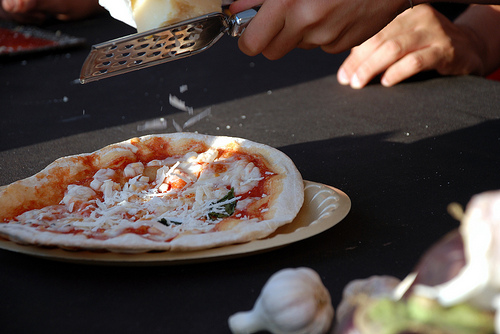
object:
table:
[0, 20, 499, 332]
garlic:
[67, 183, 94, 201]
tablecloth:
[0, 15, 499, 332]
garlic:
[443, 190, 498, 309]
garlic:
[132, 81, 221, 138]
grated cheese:
[0, 133, 286, 236]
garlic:
[226, 264, 337, 334]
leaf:
[210, 183, 267, 220]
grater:
[77, 1, 269, 89]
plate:
[0, 177, 354, 264]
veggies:
[348, 284, 494, 334]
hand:
[230, 0, 414, 60]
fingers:
[331, 24, 454, 89]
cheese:
[28, 156, 253, 232]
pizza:
[0, 128, 306, 253]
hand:
[335, 2, 480, 91]